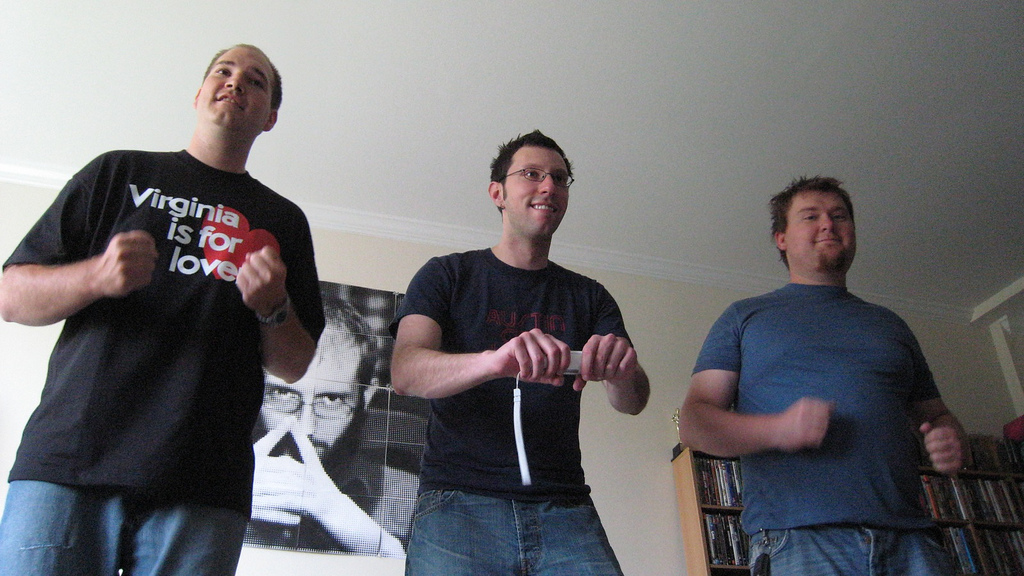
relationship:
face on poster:
[261, 290, 391, 487] [251, 278, 442, 560]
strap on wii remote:
[506, 373, 541, 481] [525, 334, 609, 379]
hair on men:
[197, 41, 289, 112] [0, 44, 325, 575]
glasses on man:
[490, 155, 579, 197] [387, 127, 679, 567]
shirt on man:
[690, 284, 961, 540] [681, 148, 1002, 570]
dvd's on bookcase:
[697, 455, 743, 504] [683, 417, 1017, 569]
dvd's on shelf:
[695, 458, 742, 507] [687, 495, 1020, 535]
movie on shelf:
[977, 533, 1001, 569] [697, 492, 1021, 538]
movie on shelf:
[706, 518, 723, 569] [687, 492, 1021, 531]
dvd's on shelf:
[695, 458, 742, 507] [693, 498, 1022, 533]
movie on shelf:
[984, 467, 1001, 522] [678, 490, 1018, 528]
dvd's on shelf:
[695, 458, 742, 507] [699, 499, 1022, 528]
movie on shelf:
[924, 474, 940, 520] [697, 492, 1021, 538]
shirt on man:
[691, 284, 961, 550] [681, 148, 1002, 570]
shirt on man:
[396, 242, 639, 510] [387, 127, 679, 567]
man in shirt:
[388, 130, 650, 574] [396, 242, 639, 510]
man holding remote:
[387, 127, 679, 567] [491, 335, 612, 491]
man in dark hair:
[387, 127, 679, 567] [481, 110, 585, 233]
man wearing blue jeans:
[378, 124, 657, 572] [371, 468, 709, 565]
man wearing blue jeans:
[657, 143, 992, 571] [7, 379, 288, 573]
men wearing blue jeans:
[0, 44, 325, 575] [688, 438, 1014, 567]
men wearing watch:
[0, 44, 325, 575] [236, 292, 303, 334]